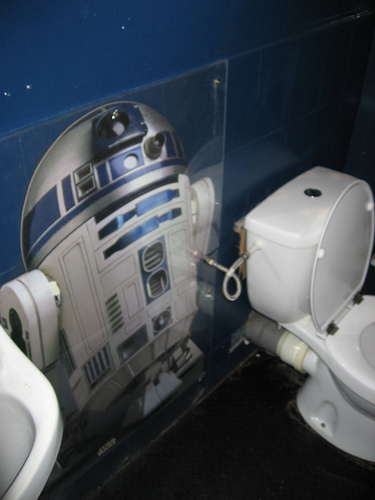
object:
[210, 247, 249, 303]
tube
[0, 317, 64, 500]
sink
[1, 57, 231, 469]
poster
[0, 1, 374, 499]
bathroom wall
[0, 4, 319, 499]
wall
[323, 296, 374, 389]
toilet seat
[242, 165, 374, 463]
white toilet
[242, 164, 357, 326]
toilet basin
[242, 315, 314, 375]
large pipe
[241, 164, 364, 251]
basin cover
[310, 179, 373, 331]
toilet lid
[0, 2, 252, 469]
plastic